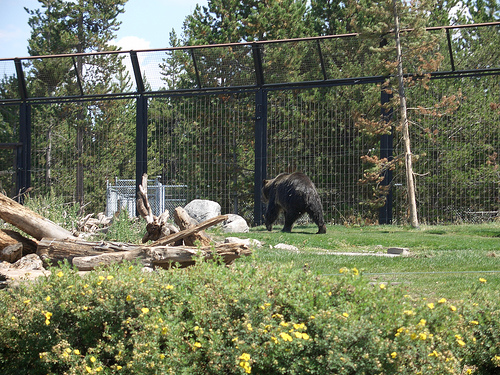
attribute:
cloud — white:
[79, 31, 176, 98]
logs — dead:
[76, 248, 207, 260]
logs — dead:
[0, 202, 57, 236]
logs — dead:
[162, 215, 232, 235]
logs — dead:
[54, 240, 91, 256]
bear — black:
[244, 147, 325, 227]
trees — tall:
[3, 1, 499, 227]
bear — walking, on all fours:
[256, 171, 329, 235]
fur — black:
[282, 174, 307, 199]